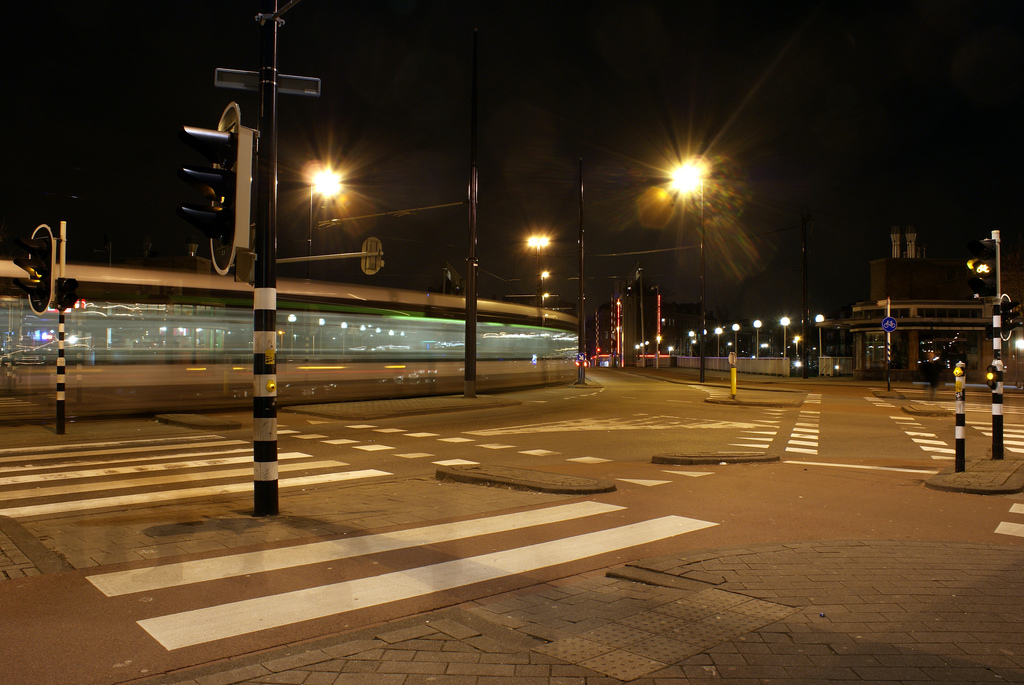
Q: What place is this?
A: It is a road.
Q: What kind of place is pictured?
A: It is a road.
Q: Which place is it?
A: It is a road.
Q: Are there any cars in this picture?
A: No, there are no cars.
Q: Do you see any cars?
A: No, there are no cars.